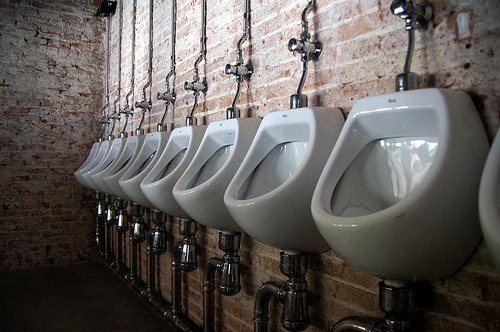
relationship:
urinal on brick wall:
[219, 103, 348, 252] [105, 6, 495, 332]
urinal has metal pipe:
[219, 103, 348, 252] [276, 0, 328, 109]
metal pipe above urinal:
[276, 0, 328, 109] [219, 103, 348, 252]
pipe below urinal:
[242, 251, 313, 331] [219, 103, 348, 252]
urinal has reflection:
[305, 85, 499, 282] [370, 141, 439, 201]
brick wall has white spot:
[105, 6, 495, 332] [451, 13, 472, 39]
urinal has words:
[219, 103, 348, 252] [279, 113, 290, 119]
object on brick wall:
[95, 3, 119, 14] [105, 6, 495, 332]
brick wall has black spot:
[105, 6, 495, 332] [462, 61, 470, 69]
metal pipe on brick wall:
[276, 0, 328, 109] [105, 6, 495, 332]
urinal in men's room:
[219, 103, 348, 252] [0, 2, 496, 331]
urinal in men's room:
[305, 85, 499, 282] [0, 2, 496, 331]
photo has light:
[2, 2, 499, 329] [103, 3, 386, 129]